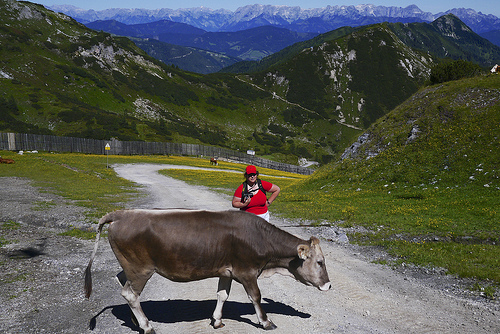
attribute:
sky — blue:
[38, 0, 497, 10]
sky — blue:
[88, 2, 497, 11]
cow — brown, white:
[84, 207, 335, 332]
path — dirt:
[104, 149, 498, 331]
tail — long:
[71, 211, 114, 294]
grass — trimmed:
[42, 149, 126, 212]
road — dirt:
[113, 160, 384, 332]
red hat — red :
[246, 161, 258, 174]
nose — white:
[325, 282, 332, 291]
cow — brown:
[56, 190, 339, 305]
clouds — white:
[278, 8, 310, 36]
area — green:
[0, 143, 133, 241]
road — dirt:
[109, 160, 496, 331]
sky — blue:
[33, 1, 498, 18]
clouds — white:
[182, 8, 248, 24]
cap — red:
[243, 162, 259, 173]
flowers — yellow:
[375, 174, 407, 208]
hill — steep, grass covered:
[279, 79, 499, 284]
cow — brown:
[86, 212, 333, 322]